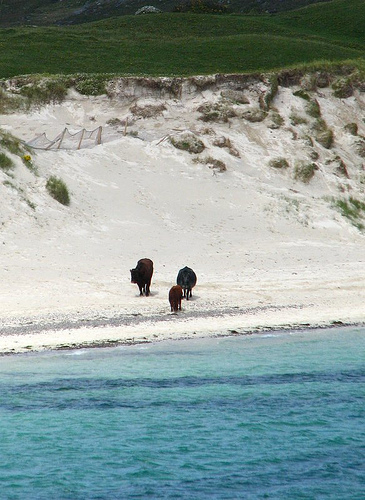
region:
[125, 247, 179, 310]
the cow is brown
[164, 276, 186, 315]
the cow is brown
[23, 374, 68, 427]
the water is blue-green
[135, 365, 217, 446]
the water is blue-green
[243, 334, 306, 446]
the water is blue-green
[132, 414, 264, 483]
the water is blue-green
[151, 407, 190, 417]
the water is blue-green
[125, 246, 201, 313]
three bison on sandy plain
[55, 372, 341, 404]
shadow cast on water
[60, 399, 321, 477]
water is blue and green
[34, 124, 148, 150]
fence on the hillside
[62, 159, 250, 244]
hillside covered with sand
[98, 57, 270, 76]
green pasture behind hill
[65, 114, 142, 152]
fence has wooden posts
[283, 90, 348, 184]
green brush on hillside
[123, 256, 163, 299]
bison is brown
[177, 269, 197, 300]
bison is black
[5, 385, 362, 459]
a blue big blue sea.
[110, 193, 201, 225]
a white ground covered with snow.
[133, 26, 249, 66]
the grass is short and green.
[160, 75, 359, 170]
a bunch of grass and rocks covered in snow.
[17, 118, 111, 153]
a thin white fence.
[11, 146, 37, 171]
a yellow and black ball.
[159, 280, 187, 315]
a small brown cow.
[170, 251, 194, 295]
a big black cow.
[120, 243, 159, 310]
a big brown cow.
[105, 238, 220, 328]
three cows are on the beach near the ocean.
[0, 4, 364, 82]
The grass is green.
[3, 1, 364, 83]
The landscape is hilly.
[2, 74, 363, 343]
The hillside is snow covered.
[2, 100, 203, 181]
The fence is falling down.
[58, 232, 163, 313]
The cow is standing on snow.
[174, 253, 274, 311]
The cow is standing on snow.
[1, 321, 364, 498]
The water is wavy.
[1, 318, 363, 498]
The water is ripply.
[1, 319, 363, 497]
The water is blue.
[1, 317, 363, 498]
The water is untroubled.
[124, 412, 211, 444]
Cold blue winter water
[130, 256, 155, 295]
Cow standing near water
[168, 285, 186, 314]
Cow standing near water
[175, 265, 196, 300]
Cow standing near water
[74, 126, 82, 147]
Fence post in snowy ground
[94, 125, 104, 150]
Fence post in snowy ground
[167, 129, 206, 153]
Rock on snowy ground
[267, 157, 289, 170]
Rock on snowy ground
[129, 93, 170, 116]
Rock on snowy ground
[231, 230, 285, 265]
PART OF COLD SNOWY GROUND